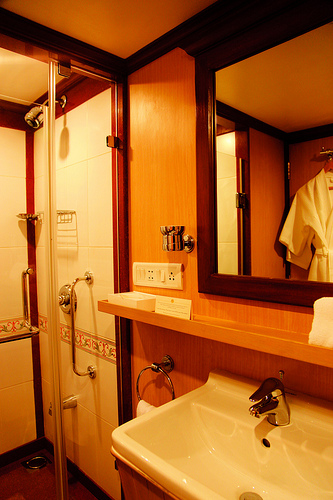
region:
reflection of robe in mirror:
[275, 177, 332, 253]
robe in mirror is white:
[297, 212, 326, 270]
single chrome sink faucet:
[247, 379, 282, 426]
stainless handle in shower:
[73, 356, 85, 376]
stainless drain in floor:
[27, 462, 59, 487]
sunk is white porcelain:
[182, 485, 198, 494]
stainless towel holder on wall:
[144, 361, 164, 372]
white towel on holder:
[134, 389, 155, 423]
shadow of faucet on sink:
[251, 415, 274, 453]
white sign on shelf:
[151, 291, 195, 330]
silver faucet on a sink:
[248, 377, 294, 429]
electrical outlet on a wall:
[134, 263, 187, 291]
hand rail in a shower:
[68, 271, 97, 379]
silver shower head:
[23, 96, 70, 129]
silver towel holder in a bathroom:
[136, 354, 175, 410]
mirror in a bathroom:
[195, 18, 331, 305]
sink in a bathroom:
[110, 367, 331, 498]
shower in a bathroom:
[1, 18, 134, 497]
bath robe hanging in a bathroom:
[276, 156, 330, 283]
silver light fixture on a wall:
[159, 221, 195, 254]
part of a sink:
[244, 428, 251, 433]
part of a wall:
[167, 358, 171, 364]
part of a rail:
[69, 346, 76, 348]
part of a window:
[253, 313, 259, 330]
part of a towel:
[313, 321, 325, 333]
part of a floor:
[60, 458, 79, 472]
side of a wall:
[96, 399, 103, 400]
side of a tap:
[254, 404, 258, 410]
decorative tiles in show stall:
[0, 313, 115, 363]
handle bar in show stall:
[68, 268, 97, 379]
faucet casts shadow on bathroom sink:
[248, 368, 289, 442]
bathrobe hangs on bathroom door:
[275, 144, 331, 284]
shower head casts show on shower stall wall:
[23, 92, 70, 159]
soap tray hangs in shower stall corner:
[14, 211, 41, 222]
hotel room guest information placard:
[154, 294, 191, 320]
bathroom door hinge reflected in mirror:
[286, 160, 290, 180]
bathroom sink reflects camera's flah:
[138, 444, 265, 492]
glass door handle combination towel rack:
[0, 267, 43, 350]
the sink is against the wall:
[111, 372, 326, 498]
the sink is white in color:
[111, 370, 328, 495]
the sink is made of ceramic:
[112, 367, 328, 496]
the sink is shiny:
[109, 368, 330, 499]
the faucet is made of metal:
[251, 378, 288, 431]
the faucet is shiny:
[250, 375, 289, 430]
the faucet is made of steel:
[249, 374, 291, 432]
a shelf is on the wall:
[98, 292, 332, 372]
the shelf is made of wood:
[98, 290, 331, 377]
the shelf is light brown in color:
[98, 287, 332, 371]